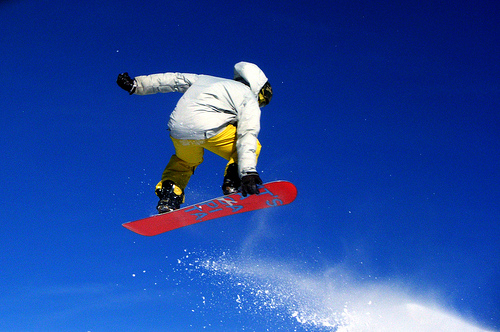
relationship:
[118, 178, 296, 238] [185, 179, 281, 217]
snowboard has graphics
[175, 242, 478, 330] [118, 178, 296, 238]
snow off snowboard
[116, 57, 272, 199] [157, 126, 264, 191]
person wearing pants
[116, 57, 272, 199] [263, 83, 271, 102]
person has goggles